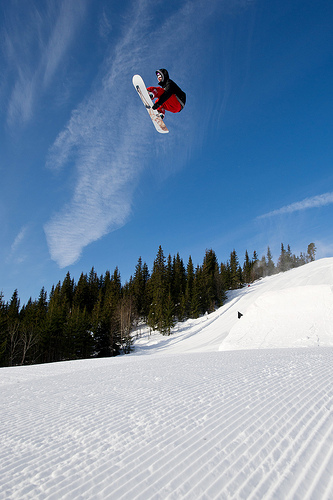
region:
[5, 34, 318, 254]
The sky is clear blue.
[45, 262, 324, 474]
The ground is snow covered.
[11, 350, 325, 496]
The ground is groomed.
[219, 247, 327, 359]
The hill is snow covered.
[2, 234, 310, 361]
The trees are green.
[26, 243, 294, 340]
The trees are evergreens.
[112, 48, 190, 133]
He is doing a trick.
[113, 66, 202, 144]
He is snow boarding.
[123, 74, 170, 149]
His board is white.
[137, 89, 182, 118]
His pants are red.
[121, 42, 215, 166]
a snowboarder in the air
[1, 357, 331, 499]
freshly raked snow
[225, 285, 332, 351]
a ramp made of snow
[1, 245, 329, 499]
a mountain slope covered in trees and snow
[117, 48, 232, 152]
a snowboarder doing a jump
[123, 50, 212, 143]
the snowboarder is on his board in the air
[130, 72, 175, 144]
a white snowboard with an orange flame design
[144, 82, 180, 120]
he is wearing red snowboard pants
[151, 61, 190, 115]
he is wearing his jacket's hood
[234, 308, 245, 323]
a black flag marker in the snow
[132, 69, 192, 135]
a person skating in the air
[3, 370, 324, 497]
the field covered with snow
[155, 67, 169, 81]
he head of the man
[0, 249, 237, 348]
many pines in the background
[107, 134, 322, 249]
a beautiful sunny sky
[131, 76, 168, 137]
the white skateboard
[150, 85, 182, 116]
the pant is red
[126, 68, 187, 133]
the person is jumping on the skateboard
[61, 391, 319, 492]
skateboards tracks on the snow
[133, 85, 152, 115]
the wheels of the skateboard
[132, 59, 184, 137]
snowboarder performing trick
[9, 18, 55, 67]
white clouds in blue sky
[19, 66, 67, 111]
white clouds in blue sky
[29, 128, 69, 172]
white clouds in blue sky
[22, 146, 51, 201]
white clouds in blue sky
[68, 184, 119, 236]
white clouds in blue sky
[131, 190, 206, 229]
white clouds in blue sky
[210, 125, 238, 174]
white clouds in blue sky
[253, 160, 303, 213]
white clouds in blue sky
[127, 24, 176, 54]
white clouds in blue sky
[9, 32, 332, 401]
picture taken outdoors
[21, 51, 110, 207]
picture taken during the day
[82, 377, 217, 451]
the snow is groomed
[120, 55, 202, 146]
a snowboarder in the air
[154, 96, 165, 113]
the skier holds onto the board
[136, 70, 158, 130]
the board is white in color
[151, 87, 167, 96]
the boarder's pants are red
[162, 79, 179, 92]
the boarder's coat is black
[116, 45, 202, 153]
the snow boarder is doing a trick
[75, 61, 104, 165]
the sky is blue with whispy clouds